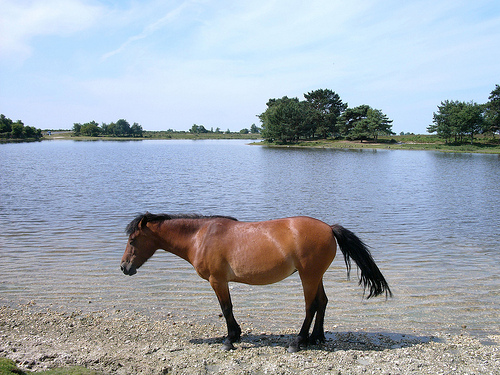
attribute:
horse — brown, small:
[115, 194, 353, 331]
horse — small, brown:
[120, 213, 391, 350]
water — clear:
[2, 138, 496, 326]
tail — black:
[334, 221, 398, 309]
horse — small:
[112, 199, 392, 349]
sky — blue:
[1, 0, 499, 136]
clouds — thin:
[0, 0, 499, 134]